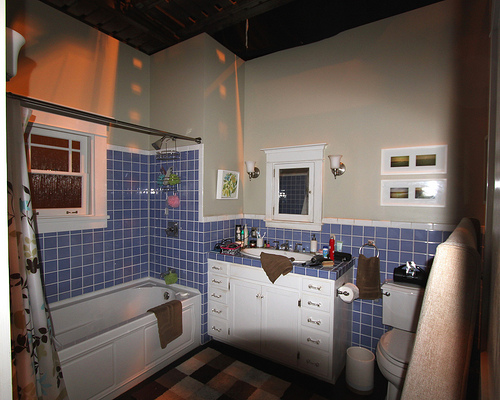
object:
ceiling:
[6, 1, 497, 69]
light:
[54, 120, 84, 126]